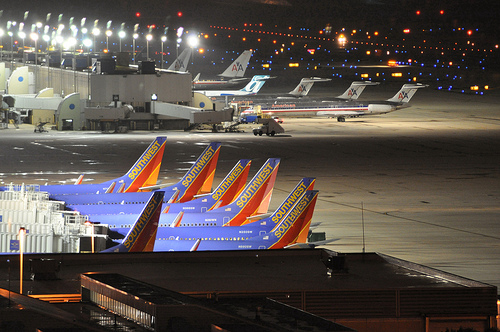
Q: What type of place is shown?
A: It is an airport.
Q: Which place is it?
A: It is an airport.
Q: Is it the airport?
A: Yes, it is the airport.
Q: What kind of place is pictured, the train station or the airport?
A: It is the airport.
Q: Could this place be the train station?
A: No, it is the airport.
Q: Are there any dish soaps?
A: No, there are no dish soaps.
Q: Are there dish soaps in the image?
A: No, there are no dish soaps.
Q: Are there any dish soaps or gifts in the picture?
A: No, there are no dish soaps or gifts.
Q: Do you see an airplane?
A: Yes, there is an airplane.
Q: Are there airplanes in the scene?
A: Yes, there is an airplane.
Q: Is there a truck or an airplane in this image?
A: Yes, there is an airplane.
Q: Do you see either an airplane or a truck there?
A: Yes, there is an airplane.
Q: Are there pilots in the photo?
A: No, there are no pilots.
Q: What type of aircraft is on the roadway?
A: The aircraft is an airplane.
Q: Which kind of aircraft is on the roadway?
A: The aircraft is an airplane.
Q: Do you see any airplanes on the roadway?
A: Yes, there is an airplane on the roadway.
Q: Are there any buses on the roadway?
A: No, there is an airplane on the roadway.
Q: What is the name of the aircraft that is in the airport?
A: The aircraft is an airplane.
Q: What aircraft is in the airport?
A: The aircraft is an airplane.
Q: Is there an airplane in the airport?
A: Yes, there is an airplane in the airport.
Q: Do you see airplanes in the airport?
A: Yes, there is an airplane in the airport.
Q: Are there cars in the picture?
A: No, there are no cars.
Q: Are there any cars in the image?
A: No, there are no cars.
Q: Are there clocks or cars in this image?
A: No, there are no cars or clocks.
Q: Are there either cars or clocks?
A: No, there are no cars or clocks.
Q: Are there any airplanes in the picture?
A: Yes, there is an airplane.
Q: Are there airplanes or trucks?
A: Yes, there is an airplane.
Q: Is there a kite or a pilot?
A: No, there are no pilots or kites.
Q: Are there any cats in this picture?
A: No, there are no cats.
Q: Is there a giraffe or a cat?
A: No, there are no cats or giraffes.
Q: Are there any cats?
A: No, there are no cats.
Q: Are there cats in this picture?
A: No, there are no cats.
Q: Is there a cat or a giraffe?
A: No, there are no cats or giraffes.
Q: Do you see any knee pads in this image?
A: No, there are no knee pads.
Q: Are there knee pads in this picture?
A: No, there are no knee pads.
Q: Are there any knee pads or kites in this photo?
A: No, there are no knee pads or kites.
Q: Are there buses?
A: No, there are no buses.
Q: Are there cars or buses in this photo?
A: No, there are no buses or cars.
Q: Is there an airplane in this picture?
A: Yes, there is an airplane.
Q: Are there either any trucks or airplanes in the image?
A: Yes, there is an airplane.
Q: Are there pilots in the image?
A: No, there are no pilots.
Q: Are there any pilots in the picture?
A: No, there are no pilots.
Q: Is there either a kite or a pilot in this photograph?
A: No, there are no pilots or kites.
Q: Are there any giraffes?
A: No, there are no giraffes.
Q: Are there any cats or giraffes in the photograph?
A: No, there are no giraffes or cats.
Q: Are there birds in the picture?
A: No, there are no birds.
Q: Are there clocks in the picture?
A: No, there are no clocks.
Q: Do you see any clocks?
A: No, there are no clocks.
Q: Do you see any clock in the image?
A: No, there are no clocks.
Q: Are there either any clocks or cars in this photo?
A: No, there are no clocks or cars.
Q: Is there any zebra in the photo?
A: No, there are no zebras.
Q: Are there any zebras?
A: No, there are no zebras.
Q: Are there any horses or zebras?
A: No, there are no zebras or horses.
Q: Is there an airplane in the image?
A: Yes, there is an airplane.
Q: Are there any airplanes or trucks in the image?
A: Yes, there is an airplane.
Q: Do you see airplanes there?
A: Yes, there is an airplane.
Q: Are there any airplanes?
A: Yes, there is an airplane.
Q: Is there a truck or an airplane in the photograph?
A: Yes, there is an airplane.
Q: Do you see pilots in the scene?
A: No, there are no pilots.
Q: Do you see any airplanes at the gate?
A: Yes, there is an airplane at the gate.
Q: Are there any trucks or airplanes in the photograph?
A: Yes, there is an airplane.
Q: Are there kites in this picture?
A: No, there are no kites.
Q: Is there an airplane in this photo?
A: Yes, there is an airplane.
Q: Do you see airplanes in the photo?
A: Yes, there is an airplane.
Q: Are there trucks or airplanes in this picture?
A: Yes, there is an airplane.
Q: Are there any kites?
A: No, there are no kites.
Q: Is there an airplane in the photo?
A: Yes, there is an airplane.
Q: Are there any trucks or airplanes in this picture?
A: Yes, there is an airplane.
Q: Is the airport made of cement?
A: Yes, the airport is made of cement.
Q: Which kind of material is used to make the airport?
A: The airport is made of cement.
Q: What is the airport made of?
A: The airport is made of concrete.